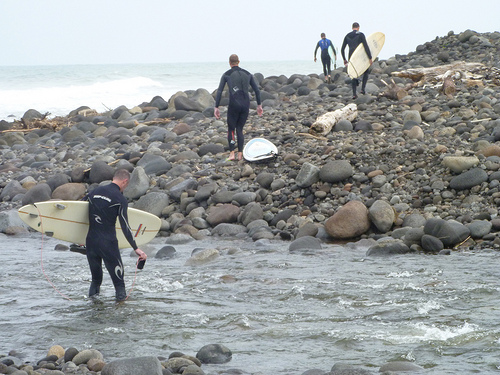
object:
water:
[206, 247, 457, 340]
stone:
[318, 143, 359, 171]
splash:
[411, 261, 471, 372]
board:
[14, 198, 166, 252]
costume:
[78, 179, 145, 299]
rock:
[310, 119, 364, 193]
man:
[79, 168, 149, 303]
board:
[240, 133, 281, 164]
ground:
[182, 116, 393, 208]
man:
[212, 53, 266, 166]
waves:
[177, 254, 340, 320]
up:
[306, 57, 426, 186]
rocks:
[322, 198, 366, 244]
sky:
[86, 14, 260, 64]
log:
[307, 100, 360, 138]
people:
[339, 21, 377, 101]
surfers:
[309, 29, 341, 85]